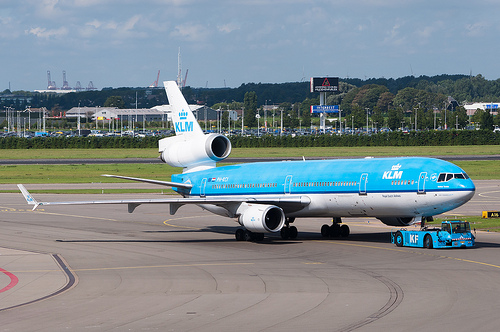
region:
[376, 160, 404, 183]
klm logo on the plant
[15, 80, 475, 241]
blue and white passenger plane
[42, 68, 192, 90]
four construction cranes on the horizon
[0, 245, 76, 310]
curved black stripe on the tarmac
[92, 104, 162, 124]
building in the distance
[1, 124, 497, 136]
large group of parked cars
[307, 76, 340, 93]
the top sign on a post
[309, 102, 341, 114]
lower sign on a post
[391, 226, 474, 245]
ground equipment towing the plane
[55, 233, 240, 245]
shadow of the wing of the plane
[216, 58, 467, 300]
a plane on the ground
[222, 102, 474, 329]
an airplane on teh ground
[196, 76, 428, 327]
a large plane on teh ground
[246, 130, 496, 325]
a large airplane on the ground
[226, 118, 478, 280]
a passenger plane on the ground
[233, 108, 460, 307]
a passenger airplane on the ground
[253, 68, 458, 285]
a large passenger plane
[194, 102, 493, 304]
a large passenger airplane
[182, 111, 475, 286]
a blue and white plane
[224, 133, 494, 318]
a white and blue airplane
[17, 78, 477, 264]
a blue and white passenger jet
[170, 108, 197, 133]
the KLM logon on the tail fin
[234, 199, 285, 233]
jet engine on the wing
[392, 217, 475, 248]
ground equipment the same color as the plane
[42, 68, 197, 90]
construction cranes in the distance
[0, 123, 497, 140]
cars parked at the airport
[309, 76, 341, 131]
a couple of signs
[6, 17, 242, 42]
a string of clouds in the sky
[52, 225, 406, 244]
the shadow of the plane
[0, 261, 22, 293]
pink stripe on the surface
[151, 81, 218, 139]
tail of the plane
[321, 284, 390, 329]
the roadway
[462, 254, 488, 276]
yellow line in the street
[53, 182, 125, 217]
wing of the plane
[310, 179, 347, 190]
windows on the plane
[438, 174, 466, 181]
the windshield on the plane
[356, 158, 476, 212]
the plan is blue and white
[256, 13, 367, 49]
clouds in the sky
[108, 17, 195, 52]
the clouds are white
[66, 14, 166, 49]
the sky is cloudy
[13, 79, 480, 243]
THIS IS A AIRPLANE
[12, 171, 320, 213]
THOSE ARE THE PLANES WINGS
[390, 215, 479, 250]
THATS A BLUE TRUCK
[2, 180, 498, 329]
THATS THE AIRPORT RUNWAY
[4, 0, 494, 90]
THIS IS THE BLUE SKY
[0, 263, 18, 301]
THATS A RED LINE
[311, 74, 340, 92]
THIS IS A BILLBOARD SIGN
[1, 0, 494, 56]
THOSE ARE SOME CLOUDS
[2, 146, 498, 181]
THIS IS SOME GRASS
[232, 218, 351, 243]
THESE ARE SOME WHEELS